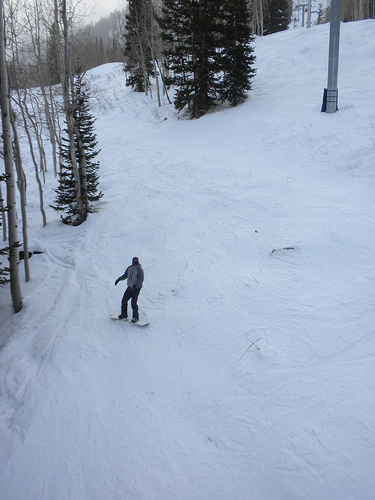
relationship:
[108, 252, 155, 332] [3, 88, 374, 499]
man in snow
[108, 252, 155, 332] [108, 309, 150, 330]
man on board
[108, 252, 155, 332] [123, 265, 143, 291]
man in jacket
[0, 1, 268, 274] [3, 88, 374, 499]
trees in snow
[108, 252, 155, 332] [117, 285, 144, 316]
man in pants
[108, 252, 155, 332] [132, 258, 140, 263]
man in hat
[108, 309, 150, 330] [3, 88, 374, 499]
board in snow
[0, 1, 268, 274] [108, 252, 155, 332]
trees behind man